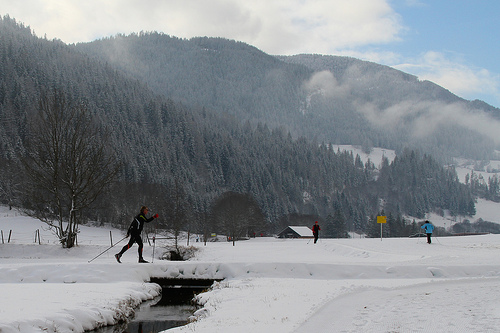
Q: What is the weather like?
A: It is cloudy.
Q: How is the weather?
A: It is cloudy.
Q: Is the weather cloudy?
A: Yes, it is cloudy.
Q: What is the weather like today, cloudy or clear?
A: It is cloudy.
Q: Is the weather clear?
A: No, it is cloudy.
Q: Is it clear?
A: No, it is cloudy.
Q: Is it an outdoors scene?
A: Yes, it is outdoors.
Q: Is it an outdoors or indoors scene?
A: It is outdoors.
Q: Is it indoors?
A: No, it is outdoors.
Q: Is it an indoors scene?
A: No, it is outdoors.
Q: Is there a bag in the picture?
A: No, there are no bags.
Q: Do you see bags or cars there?
A: No, there are no bags or cars.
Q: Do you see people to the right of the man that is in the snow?
A: Yes, there are people to the right of the man.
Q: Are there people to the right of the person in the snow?
A: Yes, there are people to the right of the man.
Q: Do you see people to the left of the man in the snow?
A: No, the people are to the right of the man.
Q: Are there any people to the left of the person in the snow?
A: No, the people are to the right of the man.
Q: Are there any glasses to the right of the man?
A: No, there are people to the right of the man.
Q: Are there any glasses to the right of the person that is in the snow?
A: No, there are people to the right of the man.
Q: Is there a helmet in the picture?
A: No, there are no helmets.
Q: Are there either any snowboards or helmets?
A: No, there are no helmets or snowboards.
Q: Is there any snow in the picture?
A: Yes, there is snow.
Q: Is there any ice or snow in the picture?
A: Yes, there is snow.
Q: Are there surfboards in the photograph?
A: No, there are no surfboards.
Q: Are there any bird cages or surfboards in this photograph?
A: No, there are no surfboards or bird cages.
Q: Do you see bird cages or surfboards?
A: No, there are no surfboards or bird cages.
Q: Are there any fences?
A: Yes, there is a fence.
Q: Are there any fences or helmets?
A: Yes, there is a fence.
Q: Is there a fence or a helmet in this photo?
A: Yes, there is a fence.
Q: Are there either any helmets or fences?
A: Yes, there is a fence.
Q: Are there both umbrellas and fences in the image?
A: No, there is a fence but no umbrellas.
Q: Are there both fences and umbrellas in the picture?
A: No, there is a fence but no umbrellas.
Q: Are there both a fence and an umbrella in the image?
A: No, there is a fence but no umbrellas.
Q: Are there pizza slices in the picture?
A: No, there are no pizza slices.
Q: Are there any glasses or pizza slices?
A: No, there are no pizza slices or glasses.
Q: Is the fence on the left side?
A: Yes, the fence is on the left of the image.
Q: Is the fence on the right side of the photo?
A: No, the fence is on the left of the image.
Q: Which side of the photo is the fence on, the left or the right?
A: The fence is on the left of the image.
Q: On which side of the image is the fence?
A: The fence is on the left of the image.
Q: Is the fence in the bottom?
A: Yes, the fence is in the bottom of the image.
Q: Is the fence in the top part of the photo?
A: No, the fence is in the bottom of the image.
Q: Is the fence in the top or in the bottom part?
A: The fence is in the bottom of the image.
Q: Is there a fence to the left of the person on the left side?
A: Yes, there is a fence to the left of the person.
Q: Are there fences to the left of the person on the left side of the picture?
A: Yes, there is a fence to the left of the person.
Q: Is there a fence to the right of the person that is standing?
A: No, the fence is to the left of the person.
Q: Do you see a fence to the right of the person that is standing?
A: No, the fence is to the left of the person.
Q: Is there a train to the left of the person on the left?
A: No, there is a fence to the left of the person.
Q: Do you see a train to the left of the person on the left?
A: No, there is a fence to the left of the person.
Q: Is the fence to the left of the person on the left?
A: Yes, the fence is to the left of the person.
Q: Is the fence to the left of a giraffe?
A: No, the fence is to the left of the person.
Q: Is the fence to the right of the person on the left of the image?
A: No, the fence is to the left of the person.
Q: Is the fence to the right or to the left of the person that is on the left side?
A: The fence is to the left of the person.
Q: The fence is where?
A: The fence is in the snow.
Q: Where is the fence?
A: The fence is in the snow.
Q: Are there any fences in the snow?
A: Yes, there is a fence in the snow.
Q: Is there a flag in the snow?
A: No, there is a fence in the snow.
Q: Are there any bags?
A: No, there are no bags.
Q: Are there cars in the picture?
A: No, there are no cars.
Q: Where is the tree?
A: The tree is in the snow.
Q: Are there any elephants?
A: No, there are no elephants.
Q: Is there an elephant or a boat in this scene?
A: No, there are no elephants or boats.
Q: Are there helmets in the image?
A: No, there are no helmets.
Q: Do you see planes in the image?
A: No, there are no planes.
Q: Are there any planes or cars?
A: No, there are no planes or cars.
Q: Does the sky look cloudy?
A: Yes, the sky is cloudy.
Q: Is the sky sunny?
A: No, the sky is cloudy.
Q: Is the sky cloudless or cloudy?
A: The sky is cloudy.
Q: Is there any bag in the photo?
A: No, there are no bags.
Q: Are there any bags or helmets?
A: No, there are no bags or helmets.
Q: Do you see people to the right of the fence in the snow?
A: Yes, there is a person to the right of the fence.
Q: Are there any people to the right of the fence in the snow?
A: Yes, there is a person to the right of the fence.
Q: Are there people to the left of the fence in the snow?
A: No, the person is to the right of the fence.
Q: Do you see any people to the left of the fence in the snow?
A: No, the person is to the right of the fence.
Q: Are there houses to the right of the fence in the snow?
A: No, there is a person to the right of the fence.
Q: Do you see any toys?
A: No, there are no toys.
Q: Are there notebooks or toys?
A: No, there are no toys or notebooks.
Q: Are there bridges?
A: Yes, there is a bridge.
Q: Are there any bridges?
A: Yes, there is a bridge.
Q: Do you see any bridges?
A: Yes, there is a bridge.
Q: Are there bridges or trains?
A: Yes, there is a bridge.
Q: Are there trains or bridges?
A: Yes, there is a bridge.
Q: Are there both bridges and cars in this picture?
A: No, there is a bridge but no cars.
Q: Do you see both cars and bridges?
A: No, there is a bridge but no cars.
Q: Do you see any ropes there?
A: No, there are no ropes.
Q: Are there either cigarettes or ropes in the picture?
A: No, there are no ropes or cigarettes.